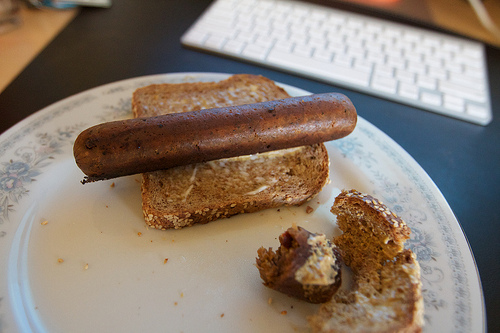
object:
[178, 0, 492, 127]
keyboard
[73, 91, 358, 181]
hot dog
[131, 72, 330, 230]
toast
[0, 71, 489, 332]
plate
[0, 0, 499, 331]
mat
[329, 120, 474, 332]
design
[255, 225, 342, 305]
hot dog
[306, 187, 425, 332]
bread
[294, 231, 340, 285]
spread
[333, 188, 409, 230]
crust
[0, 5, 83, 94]
border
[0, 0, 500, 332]
table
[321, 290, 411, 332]
butter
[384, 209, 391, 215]
sesame seed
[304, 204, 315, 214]
bread crumb